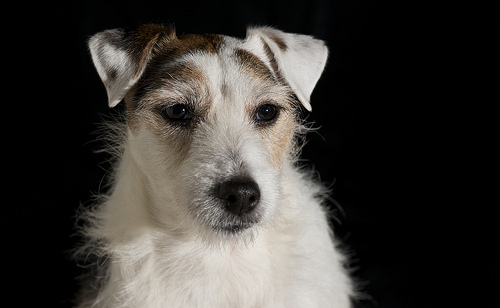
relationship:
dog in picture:
[68, 15, 368, 305] [6, 6, 493, 306]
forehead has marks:
[135, 50, 280, 90] [148, 59, 197, 88]